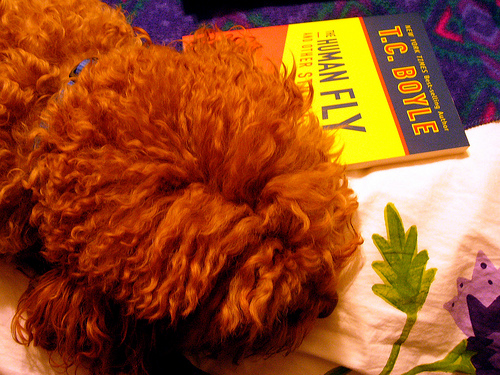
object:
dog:
[0, 2, 364, 367]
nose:
[319, 291, 340, 316]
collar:
[70, 55, 95, 78]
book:
[183, 16, 470, 175]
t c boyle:
[377, 26, 440, 135]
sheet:
[1, 120, 498, 373]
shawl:
[103, 0, 499, 131]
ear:
[14, 269, 115, 372]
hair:
[10, 274, 116, 373]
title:
[317, 32, 365, 134]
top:
[55, 57, 338, 286]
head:
[34, 34, 369, 348]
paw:
[0, 208, 34, 252]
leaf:
[372, 202, 438, 373]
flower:
[445, 252, 499, 336]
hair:
[230, 24, 249, 36]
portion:
[465, 294, 499, 374]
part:
[2, 261, 37, 374]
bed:
[1, 1, 499, 373]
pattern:
[204, 2, 499, 130]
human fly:
[317, 39, 366, 134]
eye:
[214, 260, 239, 287]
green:
[407, 337, 475, 374]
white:
[416, 325, 453, 348]